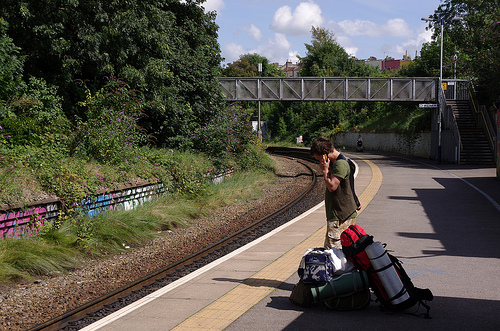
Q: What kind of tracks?
A: Railroad.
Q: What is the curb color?
A: White.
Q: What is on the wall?
A: Graffiti.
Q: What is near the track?
A: Rocks.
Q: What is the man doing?
A: Talking.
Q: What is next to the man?
A: Luggage.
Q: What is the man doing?
A: Standing.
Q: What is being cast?
A: Shadow.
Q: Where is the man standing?
A: Platform.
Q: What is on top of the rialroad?
A: Bridge.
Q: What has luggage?
A: The man has luggage.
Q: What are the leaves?
A: The leaves are green.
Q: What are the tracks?
A: The tracks are metal.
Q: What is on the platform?
A: The man and luggage.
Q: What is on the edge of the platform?
A: The white line.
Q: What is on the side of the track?
A: The gravel.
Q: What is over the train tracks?
A: The walkway.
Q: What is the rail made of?
A: Metal.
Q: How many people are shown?
A: One.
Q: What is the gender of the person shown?
A: Male.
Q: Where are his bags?
A: On the ground.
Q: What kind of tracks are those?
A: Train.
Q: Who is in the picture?
A: A man.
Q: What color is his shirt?
A: Green.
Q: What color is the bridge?
A: Grey.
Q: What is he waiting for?
A: Train.